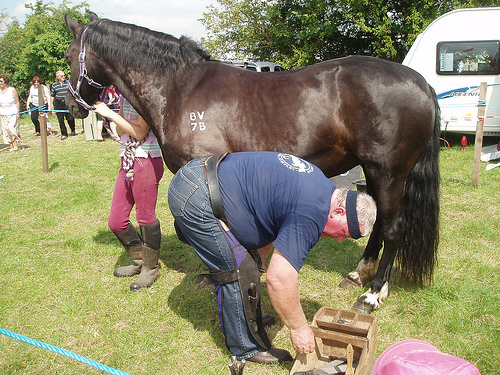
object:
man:
[169, 151, 378, 365]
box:
[289, 305, 379, 374]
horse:
[64, 11, 440, 315]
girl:
[91, 90, 165, 290]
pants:
[108, 153, 165, 232]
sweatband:
[346, 190, 366, 240]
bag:
[371, 338, 480, 374]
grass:
[0, 140, 499, 375]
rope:
[450, 92, 481, 97]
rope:
[2, 104, 71, 116]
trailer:
[402, 8, 500, 138]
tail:
[391, 83, 441, 291]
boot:
[113, 219, 161, 291]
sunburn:
[320, 218, 364, 242]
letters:
[190, 111, 207, 131]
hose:
[0, 328, 128, 374]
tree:
[196, 1, 499, 70]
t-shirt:
[216, 151, 337, 273]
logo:
[277, 153, 314, 173]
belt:
[206, 152, 229, 218]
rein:
[64, 12, 106, 119]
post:
[470, 82, 488, 186]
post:
[38, 83, 49, 173]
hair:
[334, 187, 378, 236]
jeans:
[166, 157, 266, 360]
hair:
[76, 18, 207, 73]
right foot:
[338, 260, 378, 288]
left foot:
[352, 273, 389, 312]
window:
[436, 39, 500, 77]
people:
[0, 76, 76, 152]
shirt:
[120, 93, 162, 159]